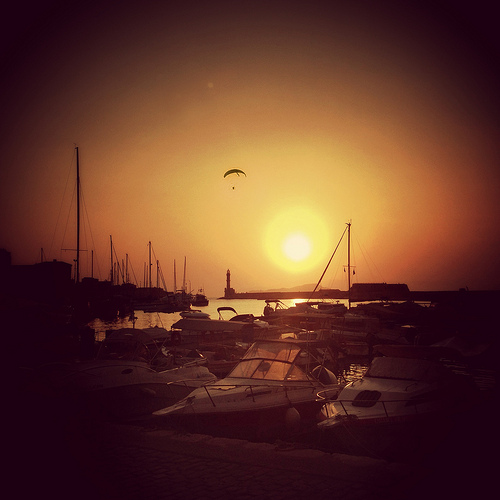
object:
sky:
[0, 0, 500, 294]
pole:
[347, 223, 351, 309]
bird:
[223, 167, 247, 178]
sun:
[280, 231, 313, 264]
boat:
[132, 289, 194, 314]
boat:
[192, 283, 210, 307]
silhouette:
[187, 279, 195, 300]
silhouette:
[31, 244, 75, 299]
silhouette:
[113, 260, 122, 293]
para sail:
[223, 168, 247, 190]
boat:
[149, 339, 349, 420]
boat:
[63, 347, 221, 406]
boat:
[313, 352, 475, 436]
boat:
[171, 316, 255, 336]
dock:
[0, 400, 500, 500]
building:
[224, 269, 236, 299]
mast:
[110, 234, 114, 283]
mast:
[183, 255, 187, 290]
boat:
[179, 307, 211, 318]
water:
[90, 296, 436, 342]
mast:
[91, 249, 94, 277]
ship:
[91, 235, 135, 322]